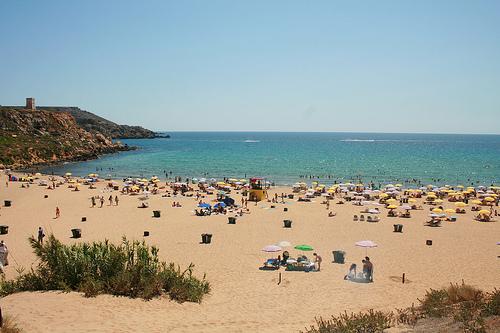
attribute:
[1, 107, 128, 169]
hill — rocky, high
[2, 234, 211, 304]
shrub — green, tall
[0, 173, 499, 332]
beach — crowded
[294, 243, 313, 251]
umbrella — green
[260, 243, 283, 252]
umbrella — white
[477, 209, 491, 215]
umbrella — yellow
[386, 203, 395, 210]
umbrella — yellow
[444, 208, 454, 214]
umbrella — yellow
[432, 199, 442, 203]
umbrella — yellow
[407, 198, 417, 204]
umbrella — yellow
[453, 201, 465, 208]
umbrella — yellow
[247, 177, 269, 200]
lifeguard stand — yellow, red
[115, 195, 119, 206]
person — walking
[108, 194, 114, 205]
person — walking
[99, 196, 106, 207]
person — walking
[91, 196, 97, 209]
person — walking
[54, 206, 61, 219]
person — walking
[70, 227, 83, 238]
trash can — black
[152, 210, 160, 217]
trash can — black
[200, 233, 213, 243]
trash can — black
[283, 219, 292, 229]
trash can — black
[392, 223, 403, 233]
trash can — black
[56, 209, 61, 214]
shirt — red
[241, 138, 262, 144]
wave — white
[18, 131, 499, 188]
ocean — clear, blue, calm, green, beautiful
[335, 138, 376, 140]
wave — white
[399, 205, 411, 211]
umbrella — yellow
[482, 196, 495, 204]
umbrella — yellow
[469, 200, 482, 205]
umbrella — yellow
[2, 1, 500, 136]
sky — clear, blue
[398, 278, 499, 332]
bush — brown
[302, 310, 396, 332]
bush — brown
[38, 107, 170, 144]
hill — high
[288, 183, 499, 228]
umbrellas — yellow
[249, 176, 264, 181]
umbrella — red